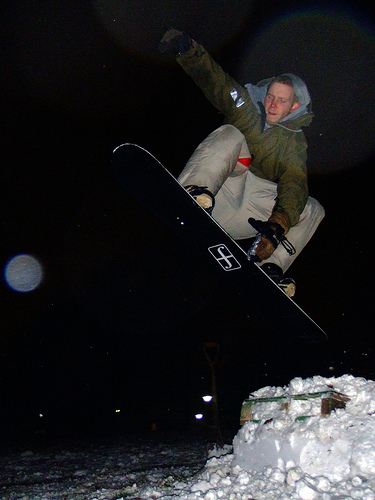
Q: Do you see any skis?
A: No, there are no skis.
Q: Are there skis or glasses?
A: No, there are no skis or glasses.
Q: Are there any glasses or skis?
A: No, there are no skis or glasses.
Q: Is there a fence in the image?
A: No, there are no fences.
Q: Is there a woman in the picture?
A: No, there are no women.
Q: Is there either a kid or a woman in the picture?
A: No, there are no women or children.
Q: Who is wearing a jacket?
A: The guy is wearing a jacket.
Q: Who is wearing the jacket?
A: The guy is wearing a jacket.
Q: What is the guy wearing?
A: The guy is wearing a jacket.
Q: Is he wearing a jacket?
A: Yes, the guy is wearing a jacket.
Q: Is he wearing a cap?
A: No, the guy is wearing a jacket.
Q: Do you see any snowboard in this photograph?
A: Yes, there is a snowboard.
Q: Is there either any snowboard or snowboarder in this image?
A: Yes, there is a snowboard.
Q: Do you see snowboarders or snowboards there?
A: Yes, there is a snowboard.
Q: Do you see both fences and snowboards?
A: No, there is a snowboard but no fences.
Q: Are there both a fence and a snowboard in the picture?
A: No, there is a snowboard but no fences.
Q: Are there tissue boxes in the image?
A: No, there are no tissue boxes.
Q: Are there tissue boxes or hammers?
A: No, there are no tissue boxes or hammers.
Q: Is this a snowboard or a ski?
A: This is a snowboard.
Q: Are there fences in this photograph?
A: No, there are no fences.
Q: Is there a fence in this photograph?
A: No, there are no fences.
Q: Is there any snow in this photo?
A: Yes, there is snow.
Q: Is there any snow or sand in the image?
A: Yes, there is snow.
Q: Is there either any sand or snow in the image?
A: Yes, there is snow.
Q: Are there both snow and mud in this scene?
A: No, there is snow but no mud.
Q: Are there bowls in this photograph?
A: No, there are no bowls.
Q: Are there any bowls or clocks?
A: No, there are no bowls or clocks.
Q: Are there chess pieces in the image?
A: No, there are no chess pieces.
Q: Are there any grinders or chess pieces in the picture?
A: No, there are no chess pieces or grinders.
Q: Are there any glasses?
A: No, there are no glasses.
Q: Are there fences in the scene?
A: No, there are no fences.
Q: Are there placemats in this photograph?
A: No, there are no placemats.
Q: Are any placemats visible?
A: No, there are no placemats.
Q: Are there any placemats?
A: No, there are no placemats.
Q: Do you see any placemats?
A: No, there are no placemats.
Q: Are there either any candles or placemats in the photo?
A: No, there are no placemats or candles.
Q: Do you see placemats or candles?
A: No, there are no placemats or candles.